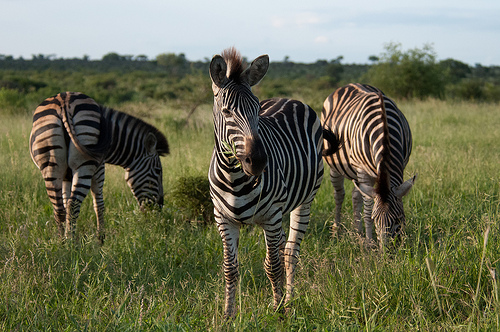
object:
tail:
[59, 96, 103, 162]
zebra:
[28, 90, 171, 242]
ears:
[238, 53, 270, 88]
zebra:
[203, 47, 339, 318]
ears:
[348, 179, 374, 202]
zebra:
[321, 81, 416, 253]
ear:
[143, 130, 157, 152]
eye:
[152, 166, 162, 175]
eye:
[219, 106, 233, 116]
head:
[121, 131, 166, 210]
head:
[206, 50, 274, 178]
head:
[352, 174, 417, 250]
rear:
[28, 91, 101, 239]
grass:
[0, 96, 498, 330]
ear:
[207, 52, 230, 87]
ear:
[393, 175, 416, 198]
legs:
[63, 163, 94, 246]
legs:
[279, 198, 311, 312]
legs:
[355, 170, 374, 242]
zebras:
[29, 47, 414, 315]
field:
[1, 42, 498, 331]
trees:
[371, 42, 428, 99]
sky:
[1, 0, 499, 68]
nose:
[244, 151, 268, 169]